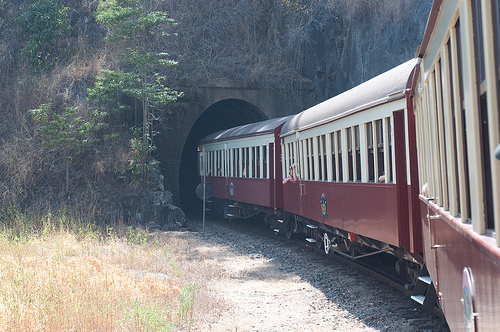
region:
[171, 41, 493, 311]
a train going into a tunnel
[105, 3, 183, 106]
the foliage of a tree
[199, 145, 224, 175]
the windows on a passenger train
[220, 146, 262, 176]
the windows on a passenger train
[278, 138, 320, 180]
the windows on a passenger train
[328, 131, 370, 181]
the windows on a passenger train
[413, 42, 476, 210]
the windows on a passenger train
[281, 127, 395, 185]
the windows on a passenger train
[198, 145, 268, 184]
the windows on a passenger train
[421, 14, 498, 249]
the windows on a passenger train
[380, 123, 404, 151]
edge of a train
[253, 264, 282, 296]
part of a ground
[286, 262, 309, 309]
edge of a shade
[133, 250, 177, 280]
part of a ground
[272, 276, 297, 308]
part of a ground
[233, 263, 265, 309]
part of a ground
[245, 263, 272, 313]
part of a ground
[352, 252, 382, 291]
part of a wheel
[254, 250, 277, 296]
edge of a shade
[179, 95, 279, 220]
concrete tunnel in mountain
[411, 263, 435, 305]
black and metal steps on red train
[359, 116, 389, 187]
windows with white trim on red train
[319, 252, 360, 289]
grey gravel beside metal train tracks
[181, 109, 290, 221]
red and white train leaving tunnel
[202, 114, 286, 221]
red and white train car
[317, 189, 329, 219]
green and yellow symbol on train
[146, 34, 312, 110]
dead vine over train tunnel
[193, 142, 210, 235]
metal pole with amber light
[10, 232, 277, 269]
dead grass by train tracks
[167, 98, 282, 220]
Arched train tunnel entrance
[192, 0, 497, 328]
Passenger train entering tunnel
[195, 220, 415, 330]
Rocks alongside of train tracks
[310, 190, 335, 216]
Business owner of train logo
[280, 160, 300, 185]
People leaning out of train car window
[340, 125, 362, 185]
Windows on train car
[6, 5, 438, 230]
Rock side of mountain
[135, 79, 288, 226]
Cement tunnel support arch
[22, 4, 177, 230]
Trees growing alongside of mountain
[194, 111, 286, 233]
Passenger train car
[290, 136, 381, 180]
row of windows on a train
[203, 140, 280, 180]
row of windows on a train car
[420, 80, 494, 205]
row of windows on a train car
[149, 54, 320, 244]
train exiting a tunnel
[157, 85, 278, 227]
dark archway of a tunnel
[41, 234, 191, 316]
tan weeds by a railroad track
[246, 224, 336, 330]
gravel by the train tracks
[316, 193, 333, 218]
circular sign on the sign of a train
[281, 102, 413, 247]
red colored passenger car on a train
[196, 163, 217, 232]
back of a sign